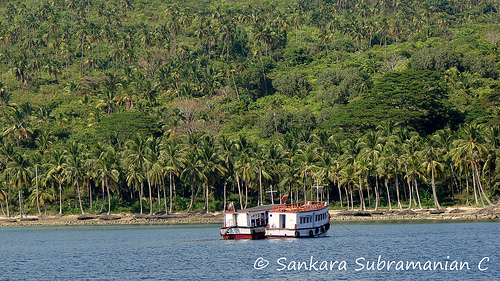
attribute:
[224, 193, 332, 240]
boat — steam, white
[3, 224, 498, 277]
water — calm, blue, ocean, lake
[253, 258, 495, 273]
print — white, first name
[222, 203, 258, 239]
boat — white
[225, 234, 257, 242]
trim — red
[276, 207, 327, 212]
railings — orange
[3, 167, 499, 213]
trees — palm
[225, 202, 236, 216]
flags — flying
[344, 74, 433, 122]
trees — deciduous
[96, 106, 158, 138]
tree — deciduous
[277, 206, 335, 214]
roof — red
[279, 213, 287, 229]
door — open